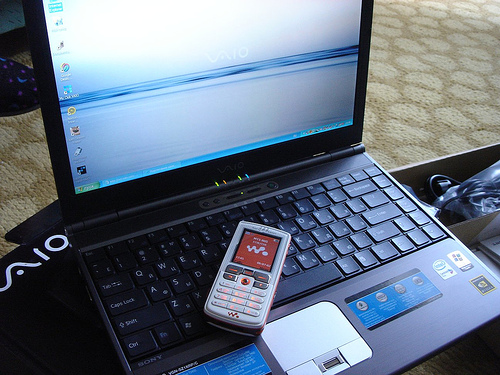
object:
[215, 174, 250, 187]
lights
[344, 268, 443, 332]
sticker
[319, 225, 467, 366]
laptop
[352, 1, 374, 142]
edge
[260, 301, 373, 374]
mouse pad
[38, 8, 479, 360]
laptop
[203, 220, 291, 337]
cellphone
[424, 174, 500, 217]
wires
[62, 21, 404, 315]
laptop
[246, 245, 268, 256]
logo